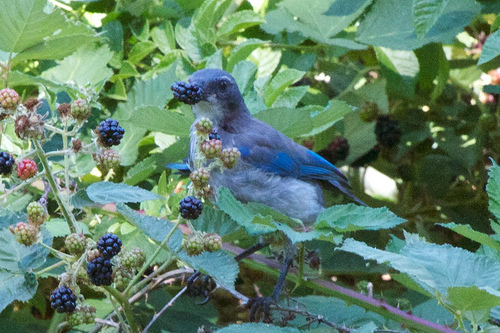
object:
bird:
[185, 67, 371, 325]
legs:
[269, 238, 298, 300]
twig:
[221, 242, 458, 332]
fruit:
[86, 257, 113, 287]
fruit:
[220, 147, 242, 170]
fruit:
[16, 158, 38, 181]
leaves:
[352, 0, 480, 52]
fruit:
[170, 81, 205, 105]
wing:
[233, 128, 370, 208]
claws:
[185, 271, 219, 305]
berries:
[202, 232, 223, 254]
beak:
[178, 82, 200, 102]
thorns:
[56, 148, 58, 151]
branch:
[0, 111, 166, 235]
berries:
[26, 201, 49, 227]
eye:
[217, 79, 229, 93]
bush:
[0, 0, 500, 333]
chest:
[189, 144, 304, 216]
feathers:
[242, 145, 322, 186]